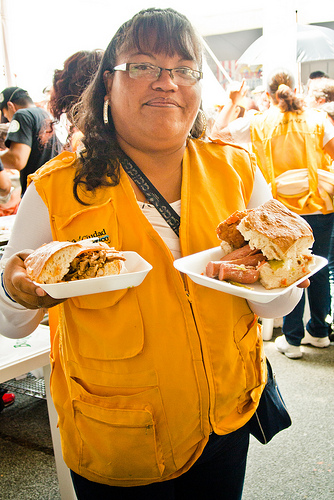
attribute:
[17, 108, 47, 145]
shirt —  person's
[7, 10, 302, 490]
woman — dark skinned